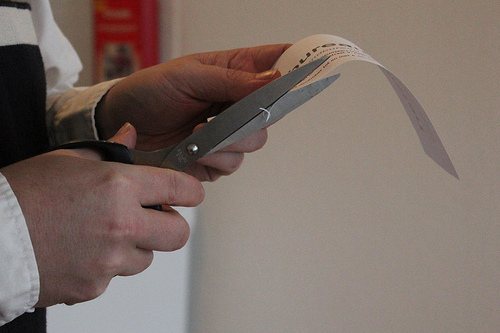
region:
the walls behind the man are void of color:
[290, 200, 405, 327]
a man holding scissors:
[80, 66, 371, 298]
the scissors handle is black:
[63, 120, 180, 220]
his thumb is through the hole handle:
[48, 118, 188, 205]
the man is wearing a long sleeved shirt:
[45, 40, 178, 220]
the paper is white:
[276, 31, 378, 77]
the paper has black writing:
[265, 15, 486, 175]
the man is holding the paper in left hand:
[111, 43, 436, 165]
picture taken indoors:
[42, 18, 497, 310]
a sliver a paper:
[247, 80, 328, 176]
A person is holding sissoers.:
[48, 36, 378, 268]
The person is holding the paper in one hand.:
[240, 13, 478, 230]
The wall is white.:
[267, 220, 467, 285]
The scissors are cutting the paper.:
[160, 35, 421, 230]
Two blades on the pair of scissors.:
[165, 38, 360, 191]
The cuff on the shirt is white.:
[1, 165, 63, 328]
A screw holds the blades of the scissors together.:
[181, 137, 200, 161]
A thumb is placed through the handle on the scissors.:
[68, 116, 144, 204]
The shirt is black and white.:
[0, 1, 115, 326]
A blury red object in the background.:
[88, 10, 164, 62]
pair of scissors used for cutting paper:
[60, 60, 339, 168]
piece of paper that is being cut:
[259, 34, 457, 181]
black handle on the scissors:
[56, 143, 135, 163]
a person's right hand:
[7, 123, 202, 301]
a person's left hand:
[96, 42, 289, 181]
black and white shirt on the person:
[3, 1, 121, 331]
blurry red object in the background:
[93, 1, 156, 79]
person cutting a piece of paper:
[0, 1, 462, 331]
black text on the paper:
[284, 40, 354, 84]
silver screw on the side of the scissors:
[187, 141, 202, 154]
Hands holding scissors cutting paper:
[46, 19, 471, 271]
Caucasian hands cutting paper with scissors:
[1, 33, 460, 308]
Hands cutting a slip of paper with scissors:
[0, 33, 460, 318]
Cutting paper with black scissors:
[4, 2, 460, 312]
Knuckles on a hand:
[92, 165, 132, 272]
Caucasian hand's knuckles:
[92, 165, 134, 272]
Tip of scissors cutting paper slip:
[293, 31, 462, 181]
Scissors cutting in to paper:
[292, 33, 462, 186]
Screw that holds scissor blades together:
[184, 140, 199, 155]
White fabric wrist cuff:
[0, 152, 47, 330]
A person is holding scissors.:
[52, 35, 350, 230]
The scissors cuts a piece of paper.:
[65, 17, 484, 221]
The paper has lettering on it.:
[267, 30, 391, 94]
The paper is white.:
[260, 29, 483, 181]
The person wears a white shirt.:
[0, 168, 65, 331]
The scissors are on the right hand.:
[35, 42, 352, 282]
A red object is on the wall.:
[75, 0, 166, 97]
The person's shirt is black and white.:
[0, 2, 83, 160]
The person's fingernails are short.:
[235, 57, 289, 96]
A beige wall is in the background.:
[212, 0, 497, 331]